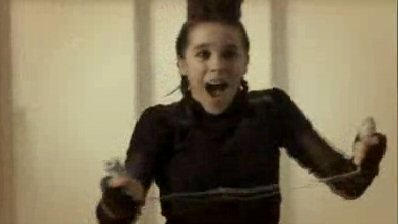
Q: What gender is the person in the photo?
A: Female.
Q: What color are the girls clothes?
A: Black.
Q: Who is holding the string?
A: The girl.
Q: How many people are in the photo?
A: One.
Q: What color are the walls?
A: White.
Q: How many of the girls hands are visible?
A: Two.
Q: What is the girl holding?
A: String.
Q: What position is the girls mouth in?
A: Open.